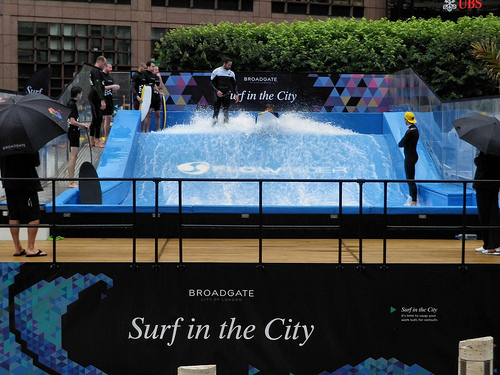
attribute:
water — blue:
[113, 107, 409, 204]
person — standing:
[394, 109, 420, 206]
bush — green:
[146, 14, 498, 72]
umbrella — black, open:
[0, 90, 77, 156]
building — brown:
[2, 0, 388, 99]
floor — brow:
[0, 236, 499, 265]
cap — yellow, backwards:
[404, 110, 417, 124]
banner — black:
[1, 260, 499, 374]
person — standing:
[207, 55, 240, 124]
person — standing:
[87, 55, 110, 149]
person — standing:
[65, 85, 90, 188]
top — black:
[397, 125, 419, 153]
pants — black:
[403, 153, 418, 201]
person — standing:
[134, 62, 155, 132]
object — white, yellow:
[139, 85, 156, 121]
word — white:
[189, 286, 255, 301]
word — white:
[128, 314, 185, 347]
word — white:
[185, 316, 214, 343]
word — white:
[215, 316, 256, 341]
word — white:
[264, 315, 314, 347]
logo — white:
[175, 159, 349, 179]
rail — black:
[0, 176, 499, 274]